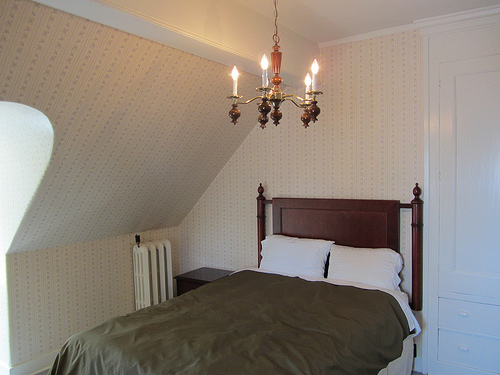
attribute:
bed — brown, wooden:
[45, 180, 429, 374]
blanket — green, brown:
[44, 268, 411, 373]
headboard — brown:
[255, 182, 427, 312]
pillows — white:
[256, 230, 407, 291]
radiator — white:
[131, 236, 175, 310]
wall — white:
[4, 225, 179, 366]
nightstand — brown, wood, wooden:
[173, 265, 234, 297]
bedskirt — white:
[372, 333, 413, 374]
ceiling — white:
[240, 1, 498, 40]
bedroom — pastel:
[2, 2, 496, 372]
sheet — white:
[245, 266, 421, 334]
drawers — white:
[436, 297, 500, 370]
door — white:
[415, 17, 500, 297]